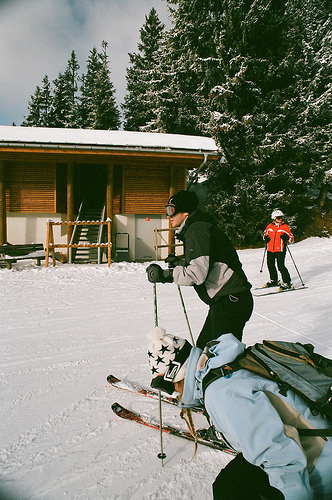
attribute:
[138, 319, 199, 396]
cap — white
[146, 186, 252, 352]
man — gray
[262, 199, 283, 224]
helmet — white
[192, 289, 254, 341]
pants — black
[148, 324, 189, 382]
hat — white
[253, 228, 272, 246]
hand — skier's hand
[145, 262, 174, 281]
glove — black, grey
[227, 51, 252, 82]
blue jacket — light blue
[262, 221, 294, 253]
red coat — white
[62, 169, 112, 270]
stairs — coming out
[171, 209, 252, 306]
jacket — green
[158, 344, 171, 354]
star — black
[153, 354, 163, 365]
star — black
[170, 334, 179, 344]
star — black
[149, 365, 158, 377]
star — black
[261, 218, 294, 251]
jacket — red